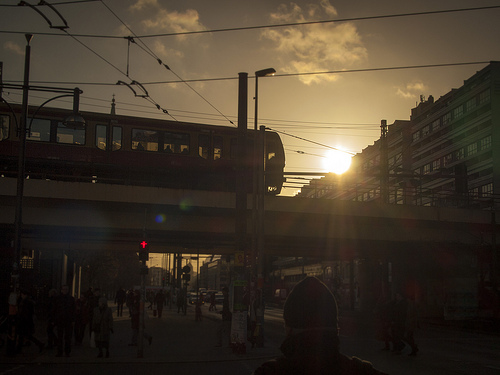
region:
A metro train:
[0, 102, 285, 194]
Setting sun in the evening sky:
[320, 143, 349, 174]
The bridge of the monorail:
[0, 178, 498, 253]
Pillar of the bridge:
[222, 253, 267, 348]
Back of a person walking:
[263, 277, 370, 373]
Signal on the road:
[137, 238, 148, 260]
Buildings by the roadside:
[200, 63, 499, 305]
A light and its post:
[254, 68, 274, 128]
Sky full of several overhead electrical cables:
[0, 0, 498, 194]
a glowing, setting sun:
[311, 138, 352, 178]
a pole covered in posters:
[228, 239, 255, 354]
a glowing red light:
[136, 238, 150, 250]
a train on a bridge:
[6, 96, 300, 209]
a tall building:
[346, 75, 490, 317]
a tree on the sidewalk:
[61, 248, 135, 309]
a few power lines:
[280, 118, 383, 136]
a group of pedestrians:
[106, 279, 181, 324]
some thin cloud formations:
[267, 0, 369, 91]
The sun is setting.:
[312, 136, 362, 180]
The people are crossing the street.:
[365, 275, 430, 366]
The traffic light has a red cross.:
[132, 231, 152, 272]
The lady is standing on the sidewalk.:
[83, 287, 119, 366]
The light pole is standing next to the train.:
[239, 51, 276, 353]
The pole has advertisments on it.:
[221, 244, 260, 352]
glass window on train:
[210, 137, 222, 159]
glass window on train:
[264, 138, 279, 163]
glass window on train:
[196, 129, 208, 159]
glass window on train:
[176, 130, 191, 155]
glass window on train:
[156, 125, 171, 151]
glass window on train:
[131, 124, 156, 152]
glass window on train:
[111, 120, 123, 152]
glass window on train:
[93, 122, 105, 150]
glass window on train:
[57, 117, 85, 144]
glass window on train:
[18, 116, 50, 144]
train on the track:
[2, 108, 309, 185]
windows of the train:
[0, 136, 246, 160]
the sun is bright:
[307, 130, 361, 175]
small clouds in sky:
[272, 1, 354, 87]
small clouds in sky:
[132, 0, 207, 42]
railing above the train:
[25, 5, 473, 77]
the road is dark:
[197, 317, 331, 363]